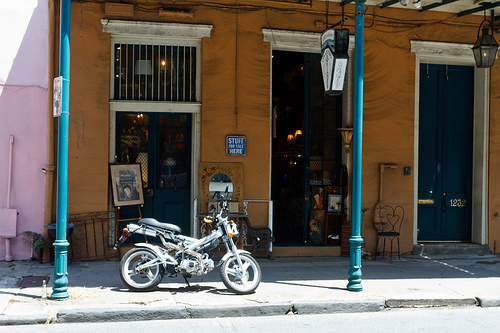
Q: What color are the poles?
A: Blue.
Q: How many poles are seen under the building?
A: 2.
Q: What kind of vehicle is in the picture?
A: A motorcycle.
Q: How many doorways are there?
A: 3.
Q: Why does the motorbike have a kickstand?
A: Hold up parked bike.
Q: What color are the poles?
A: Blue.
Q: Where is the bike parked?
A: Sidewalk.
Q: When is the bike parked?
A: Sunny day.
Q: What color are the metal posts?
A: Blue.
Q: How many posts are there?
A: Two.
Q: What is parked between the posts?
A: A motorcycle.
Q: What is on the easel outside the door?
A: A painting.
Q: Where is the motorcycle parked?
A: Between the posts.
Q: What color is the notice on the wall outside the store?
A: Blue and white.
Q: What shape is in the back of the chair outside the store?
A: A heart.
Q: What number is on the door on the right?
A: 1232.